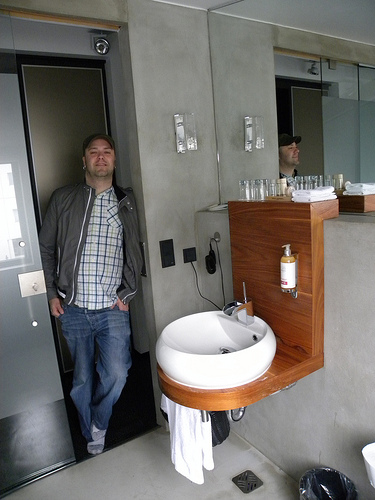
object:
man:
[42, 135, 143, 449]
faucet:
[222, 281, 251, 317]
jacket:
[41, 185, 143, 302]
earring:
[82, 165, 86, 170]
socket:
[183, 247, 197, 263]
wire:
[190, 260, 222, 311]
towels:
[292, 186, 336, 204]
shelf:
[228, 201, 339, 248]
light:
[173, 111, 197, 155]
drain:
[228, 468, 264, 493]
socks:
[86, 425, 105, 456]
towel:
[158, 394, 215, 486]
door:
[0, 51, 155, 465]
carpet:
[302, 460, 361, 499]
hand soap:
[279, 244, 296, 291]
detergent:
[236, 176, 294, 205]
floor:
[0, 424, 299, 500]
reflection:
[206, 8, 373, 198]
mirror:
[208, 4, 372, 217]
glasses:
[240, 173, 344, 200]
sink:
[155, 309, 276, 391]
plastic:
[293, 455, 362, 497]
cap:
[82, 132, 113, 151]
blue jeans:
[56, 303, 132, 439]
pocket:
[116, 308, 128, 324]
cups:
[236, 173, 335, 200]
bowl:
[155, 310, 277, 390]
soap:
[279, 243, 297, 293]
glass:
[173, 110, 198, 152]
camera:
[92, 37, 111, 56]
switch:
[159, 239, 176, 268]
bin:
[292, 459, 359, 499]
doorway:
[0, 16, 163, 497]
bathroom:
[0, 2, 374, 499]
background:
[60, 20, 177, 152]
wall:
[0, 0, 375, 499]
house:
[0, 0, 375, 499]